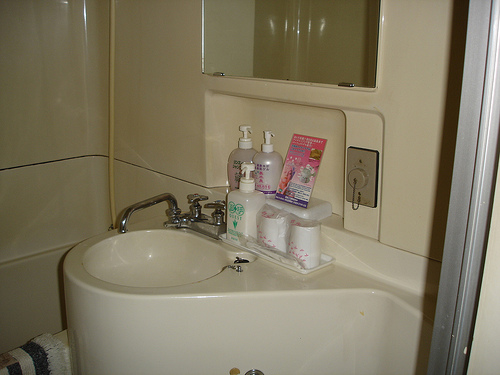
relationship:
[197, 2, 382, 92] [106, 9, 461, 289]
mirror on wall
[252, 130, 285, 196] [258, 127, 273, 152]
bottle with pump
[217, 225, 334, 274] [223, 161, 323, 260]
tray with toiletries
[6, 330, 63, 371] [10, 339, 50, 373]
bath mat with stripes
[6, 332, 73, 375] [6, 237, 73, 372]
bath mat hanging on tub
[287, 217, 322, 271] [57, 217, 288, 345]
cup on sink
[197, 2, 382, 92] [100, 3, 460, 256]
mirror on wall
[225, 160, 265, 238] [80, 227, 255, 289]
bottle next to basin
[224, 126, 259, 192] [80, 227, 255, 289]
bathroom accessories next to basin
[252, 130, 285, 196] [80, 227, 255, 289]
bottle next to basin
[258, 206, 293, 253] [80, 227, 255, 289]
cup next to basin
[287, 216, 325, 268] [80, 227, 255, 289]
cup next to basin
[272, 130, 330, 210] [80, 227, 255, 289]
brochure next to basin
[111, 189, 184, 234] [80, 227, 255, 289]
faucet on basin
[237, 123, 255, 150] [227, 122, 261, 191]
pump lid on bottle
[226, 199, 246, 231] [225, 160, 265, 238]
writing on bottle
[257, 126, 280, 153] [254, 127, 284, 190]
pump lid on bottle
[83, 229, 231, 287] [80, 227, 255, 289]
basin on basin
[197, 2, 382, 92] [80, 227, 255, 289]
mirror above basin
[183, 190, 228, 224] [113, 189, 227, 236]
handles on faucet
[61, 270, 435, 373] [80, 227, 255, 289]
wall on basin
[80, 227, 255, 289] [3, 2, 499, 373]
basin in bathroom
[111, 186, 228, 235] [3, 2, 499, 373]
faucet in bathroom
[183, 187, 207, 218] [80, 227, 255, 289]
handle on basin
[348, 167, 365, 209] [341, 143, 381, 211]
cover on outlet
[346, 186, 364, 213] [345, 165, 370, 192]
chain on cover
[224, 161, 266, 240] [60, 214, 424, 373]
bottle for sink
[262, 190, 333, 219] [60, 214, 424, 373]
soap for sink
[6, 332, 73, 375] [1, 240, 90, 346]
bath mat over tub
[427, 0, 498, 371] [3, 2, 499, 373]
doorway to bathroom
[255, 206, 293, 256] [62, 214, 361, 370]
cup sitting on sink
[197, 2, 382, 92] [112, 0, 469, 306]
mirror on wall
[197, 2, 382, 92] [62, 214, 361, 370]
mirror above sink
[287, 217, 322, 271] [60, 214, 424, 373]
cup on sink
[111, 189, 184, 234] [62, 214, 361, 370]
faucet of sink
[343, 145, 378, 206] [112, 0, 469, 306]
socket on wall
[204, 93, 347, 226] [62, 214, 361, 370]
cut out above sink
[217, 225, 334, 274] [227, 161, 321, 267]
tray with bathroom accessories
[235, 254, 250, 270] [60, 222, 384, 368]
drain plug for sink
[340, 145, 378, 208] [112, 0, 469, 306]
plug on wall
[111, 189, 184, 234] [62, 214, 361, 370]
faucet behind sink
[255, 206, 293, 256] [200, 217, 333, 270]
cup on counter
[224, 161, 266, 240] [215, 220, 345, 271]
bottle on counter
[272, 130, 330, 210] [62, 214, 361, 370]
brochure on sink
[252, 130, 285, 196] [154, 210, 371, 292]
bottle on counter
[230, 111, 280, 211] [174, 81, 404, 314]
bottle on counter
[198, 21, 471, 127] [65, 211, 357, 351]
mirror over sink